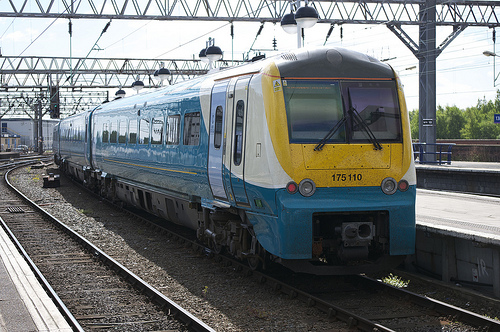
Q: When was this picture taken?
A: Daytime.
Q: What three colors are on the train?
A: Blue, white, and yellow.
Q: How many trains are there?
A: One.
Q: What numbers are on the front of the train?
A: 175110.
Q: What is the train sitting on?
A: Tracks.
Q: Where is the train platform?
A: On the right.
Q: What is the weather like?
A: Sunny.